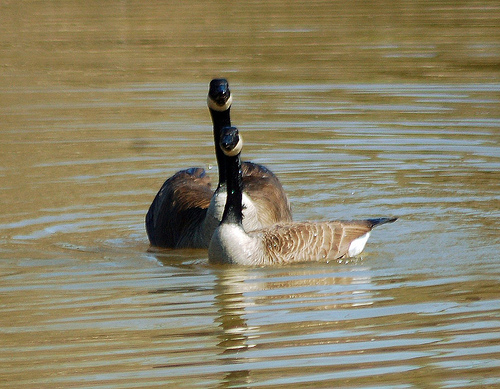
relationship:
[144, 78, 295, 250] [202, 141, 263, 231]
bird have long neck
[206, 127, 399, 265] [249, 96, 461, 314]
bird in water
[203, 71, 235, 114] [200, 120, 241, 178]
head and neck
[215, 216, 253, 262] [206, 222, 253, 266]
feathers across chest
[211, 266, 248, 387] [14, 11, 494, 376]
goose reflection in water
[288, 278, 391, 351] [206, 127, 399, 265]
ripples in bird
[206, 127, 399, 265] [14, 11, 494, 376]
bird in water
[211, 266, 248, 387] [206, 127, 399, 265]
goose reflection of bird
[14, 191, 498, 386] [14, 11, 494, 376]
ridges are across water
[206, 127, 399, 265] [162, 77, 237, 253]
bird in front of goose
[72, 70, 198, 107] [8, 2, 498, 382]
reflection on shore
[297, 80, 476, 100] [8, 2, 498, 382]
reflection on shore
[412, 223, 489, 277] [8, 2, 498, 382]
reflection on shore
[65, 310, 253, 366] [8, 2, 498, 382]
reflection on shore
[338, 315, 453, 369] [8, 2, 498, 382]
reflection on shore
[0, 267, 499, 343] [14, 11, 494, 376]
ripple in water